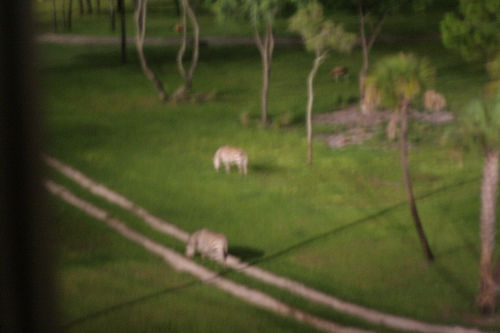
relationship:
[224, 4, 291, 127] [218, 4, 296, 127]
tree of a tree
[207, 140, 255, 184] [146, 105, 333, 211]
animal standing in field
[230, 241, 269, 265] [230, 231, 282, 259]
shadow cast ground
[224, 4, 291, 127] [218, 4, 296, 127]
tree of tree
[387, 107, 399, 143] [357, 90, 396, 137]
logs laying nex each other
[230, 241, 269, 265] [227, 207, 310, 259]
shadow along side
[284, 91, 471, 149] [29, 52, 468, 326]
pond in grass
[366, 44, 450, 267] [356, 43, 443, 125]
tree has a leaf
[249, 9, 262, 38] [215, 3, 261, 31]
twig has leaves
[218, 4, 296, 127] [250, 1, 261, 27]
tree has small twig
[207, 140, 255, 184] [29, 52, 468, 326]
sheep feeding on grass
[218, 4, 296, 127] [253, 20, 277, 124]
tree seen a stem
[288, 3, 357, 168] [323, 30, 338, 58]
tree has branches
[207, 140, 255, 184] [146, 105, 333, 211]
zebra in a field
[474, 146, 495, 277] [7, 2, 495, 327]
large tree in field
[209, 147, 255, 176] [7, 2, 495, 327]
animal in a field